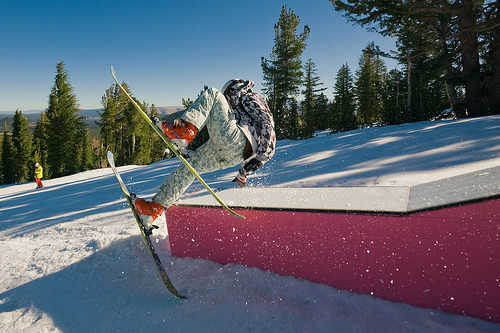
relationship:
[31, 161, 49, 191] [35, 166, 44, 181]
skier wearing jacket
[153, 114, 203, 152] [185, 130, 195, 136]
ski boot with accent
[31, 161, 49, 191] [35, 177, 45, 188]
skier wearing pants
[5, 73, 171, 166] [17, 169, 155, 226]
trees with shadows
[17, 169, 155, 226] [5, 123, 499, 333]
shadows on snow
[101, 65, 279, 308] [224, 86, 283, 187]
skier wearing jacket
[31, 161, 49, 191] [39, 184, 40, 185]
skier wearing red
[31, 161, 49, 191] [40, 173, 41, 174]
skier wearing yellow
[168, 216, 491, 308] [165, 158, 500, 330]
base on platform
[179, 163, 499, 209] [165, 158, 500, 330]
top on platform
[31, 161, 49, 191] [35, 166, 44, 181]
person wearing jacket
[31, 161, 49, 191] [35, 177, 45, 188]
person wearing pants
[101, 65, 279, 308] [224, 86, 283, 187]
man wearing jacket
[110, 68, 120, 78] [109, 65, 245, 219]
end of ski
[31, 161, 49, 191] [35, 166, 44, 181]
man in jacket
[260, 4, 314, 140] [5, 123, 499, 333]
tree in snow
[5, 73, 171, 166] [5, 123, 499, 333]
trees in snow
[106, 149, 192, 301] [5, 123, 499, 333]
ski in snow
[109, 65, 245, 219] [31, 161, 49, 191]
ski on skier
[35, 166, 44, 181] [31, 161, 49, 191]
jacket on man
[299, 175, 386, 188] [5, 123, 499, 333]
foot prints on snow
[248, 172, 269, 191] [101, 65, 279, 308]
snow off guy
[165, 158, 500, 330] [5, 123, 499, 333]
table in snow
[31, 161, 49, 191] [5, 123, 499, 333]
skier in snow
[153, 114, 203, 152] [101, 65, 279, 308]
boot on skier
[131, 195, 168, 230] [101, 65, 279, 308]
boot on skier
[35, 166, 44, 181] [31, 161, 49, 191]
jacket on skier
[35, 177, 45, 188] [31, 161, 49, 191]
pants on skier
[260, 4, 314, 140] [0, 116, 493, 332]
tree on mountain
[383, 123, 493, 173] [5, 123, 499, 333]
shadow in snow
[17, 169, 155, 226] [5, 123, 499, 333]
shadows in snow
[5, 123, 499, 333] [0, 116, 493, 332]
snow on mountain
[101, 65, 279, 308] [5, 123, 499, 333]
skier on snow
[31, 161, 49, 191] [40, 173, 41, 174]
skier in yellow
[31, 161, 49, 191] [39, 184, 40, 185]
skier in red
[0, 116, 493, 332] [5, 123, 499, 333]
hill of snow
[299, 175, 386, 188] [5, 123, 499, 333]
tracks in snow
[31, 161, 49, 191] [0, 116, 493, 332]
skier on slope